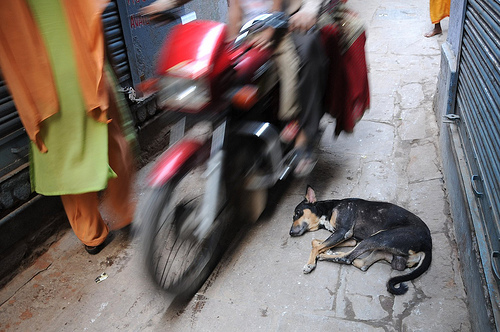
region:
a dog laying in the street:
[291, 184, 436, 296]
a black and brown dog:
[291, 181, 435, 299]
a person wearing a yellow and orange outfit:
[2, 0, 152, 255]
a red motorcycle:
[137, 9, 384, 299]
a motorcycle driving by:
[132, 10, 372, 292]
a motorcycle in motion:
[122, 13, 374, 304]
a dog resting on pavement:
[289, 182, 436, 299]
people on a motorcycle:
[134, 0, 370, 309]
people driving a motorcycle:
[132, 3, 372, 328]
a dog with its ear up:
[291, 184, 435, 296]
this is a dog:
[224, 154, 496, 310]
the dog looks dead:
[292, 189, 439, 305]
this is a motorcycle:
[115, 42, 288, 294]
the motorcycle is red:
[124, 31, 301, 280]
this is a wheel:
[107, 156, 279, 320]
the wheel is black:
[146, 169, 208, 246]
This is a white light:
[130, 78, 204, 191]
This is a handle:
[232, 26, 315, 163]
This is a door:
[411, 160, 463, 166]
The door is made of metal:
[460, 125, 485, 307]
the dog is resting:
[267, 182, 465, 308]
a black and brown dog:
[290, 186, 462, 306]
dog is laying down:
[232, 163, 451, 329]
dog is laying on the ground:
[247, 165, 444, 297]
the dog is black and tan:
[242, 170, 444, 308]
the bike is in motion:
[87, 5, 374, 301]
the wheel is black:
[114, 167, 239, 312]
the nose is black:
[271, 221, 301, 238]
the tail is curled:
[369, 256, 444, 309]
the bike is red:
[121, 2, 309, 156]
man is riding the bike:
[135, 1, 363, 161]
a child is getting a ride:
[182, 1, 320, 148]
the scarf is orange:
[5, 9, 126, 134]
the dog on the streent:
[290, 186, 455, 296]